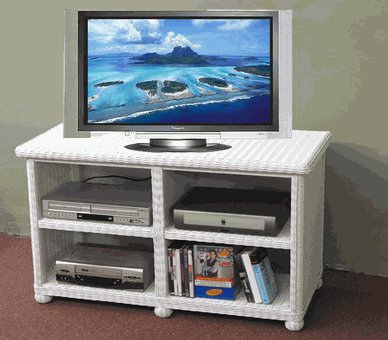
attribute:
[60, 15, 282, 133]
television — on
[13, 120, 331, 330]
stand — white